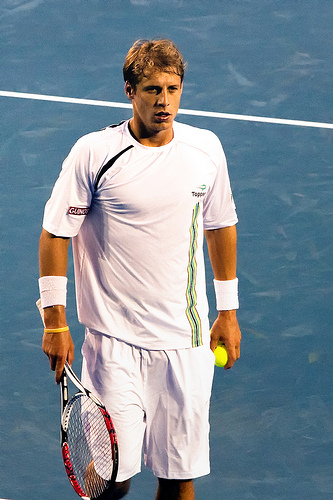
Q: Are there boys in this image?
A: No, there are no boys.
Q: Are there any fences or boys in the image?
A: No, there are no boys or fences.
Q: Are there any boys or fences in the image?
A: No, there are no boys or fences.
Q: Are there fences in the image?
A: No, there are no fences.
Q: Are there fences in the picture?
A: No, there are no fences.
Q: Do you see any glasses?
A: No, there are no glasses.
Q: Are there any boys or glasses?
A: No, there are no glasses or boys.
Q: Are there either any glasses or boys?
A: No, there are no glasses or boys.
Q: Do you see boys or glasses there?
A: No, there are no glasses or boys.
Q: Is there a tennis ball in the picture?
A: Yes, there is a tennis ball.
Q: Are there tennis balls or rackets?
A: Yes, there is a tennis ball.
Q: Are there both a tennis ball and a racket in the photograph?
A: Yes, there are both a tennis ball and a racket.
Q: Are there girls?
A: No, there are no girls.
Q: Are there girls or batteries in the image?
A: No, there are no girls or batteries.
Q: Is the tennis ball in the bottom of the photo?
A: Yes, the tennis ball is in the bottom of the image.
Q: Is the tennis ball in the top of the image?
A: No, the tennis ball is in the bottom of the image.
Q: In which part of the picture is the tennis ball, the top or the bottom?
A: The tennis ball is in the bottom of the image.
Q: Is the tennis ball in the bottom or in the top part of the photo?
A: The tennis ball is in the bottom of the image.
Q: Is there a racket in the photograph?
A: Yes, there is a racket.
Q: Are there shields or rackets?
A: Yes, there is a racket.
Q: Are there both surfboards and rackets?
A: No, there is a racket but no surfboards.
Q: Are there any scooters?
A: No, there are no scooters.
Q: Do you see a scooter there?
A: No, there are no scooters.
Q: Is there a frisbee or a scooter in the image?
A: No, there are no scooters or frisbees.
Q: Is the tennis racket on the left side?
A: Yes, the tennis racket is on the left of the image.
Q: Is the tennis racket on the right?
A: No, the tennis racket is on the left of the image.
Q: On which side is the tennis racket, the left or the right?
A: The tennis racket is on the left of the image.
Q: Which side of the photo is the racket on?
A: The racket is on the left of the image.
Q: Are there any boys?
A: No, there are no boys.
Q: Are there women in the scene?
A: No, there are no women.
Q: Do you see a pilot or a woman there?
A: No, there are no women or pilots.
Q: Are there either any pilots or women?
A: No, there are no women or pilots.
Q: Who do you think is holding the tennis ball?
A: The man is holding the tennis ball.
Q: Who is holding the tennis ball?
A: The man is holding the tennis ball.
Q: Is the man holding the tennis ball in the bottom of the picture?
A: Yes, the man is holding the tennis ball.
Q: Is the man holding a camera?
A: No, the man is holding the tennis ball.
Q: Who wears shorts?
A: The man wears shorts.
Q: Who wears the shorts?
A: The man wears shorts.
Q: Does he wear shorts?
A: Yes, the man wears shorts.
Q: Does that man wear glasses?
A: No, the man wears shorts.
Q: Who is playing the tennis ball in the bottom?
A: The man is playing the tennis ball.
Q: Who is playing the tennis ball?
A: The man is playing the tennis ball.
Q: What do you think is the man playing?
A: The man is playing the tennis ball.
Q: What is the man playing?
A: The man is playing the tennis ball.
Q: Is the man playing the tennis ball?
A: Yes, the man is playing the tennis ball.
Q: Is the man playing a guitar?
A: No, the man is playing the tennis ball.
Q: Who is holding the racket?
A: The man is holding the racket.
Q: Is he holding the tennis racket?
A: Yes, the man is holding the tennis racket.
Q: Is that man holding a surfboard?
A: No, the man is holding the tennis racket.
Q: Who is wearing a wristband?
A: The man is wearing a wristband.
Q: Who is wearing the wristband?
A: The man is wearing a wristband.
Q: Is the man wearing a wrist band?
A: Yes, the man is wearing a wrist band.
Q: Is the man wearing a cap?
A: No, the man is wearing a wrist band.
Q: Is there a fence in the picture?
A: No, there are no fences.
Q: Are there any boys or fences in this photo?
A: No, there are no fences or boys.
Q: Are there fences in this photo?
A: No, there are no fences.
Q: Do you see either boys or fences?
A: No, there are no fences or boys.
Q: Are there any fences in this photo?
A: No, there are no fences.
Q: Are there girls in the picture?
A: No, there are no girls.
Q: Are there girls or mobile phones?
A: No, there are no girls or mobile phones.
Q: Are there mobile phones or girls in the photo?
A: No, there are no girls or mobile phones.